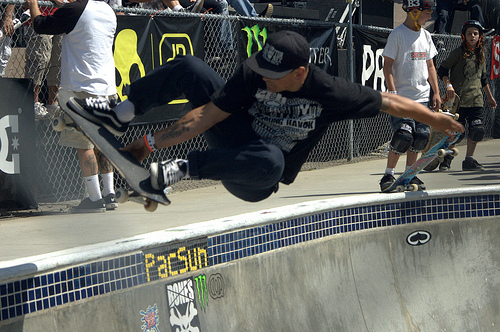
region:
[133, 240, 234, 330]
Advertisements on the half pike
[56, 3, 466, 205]
Man skatingboarding wearing all black and white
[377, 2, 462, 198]
Young boy preparing to skateboard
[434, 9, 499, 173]
Young child watching other skateboarders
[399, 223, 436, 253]
Black spade with white background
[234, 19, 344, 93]
Monster advertisement along the fence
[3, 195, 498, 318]
Blue checkered trim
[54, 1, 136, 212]
Man talking to people in the crowd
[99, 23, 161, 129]
Large yellow skull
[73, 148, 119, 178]
Tattoos on the man's leg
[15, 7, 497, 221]
this guy is stunt skating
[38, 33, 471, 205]
he is a skateboarder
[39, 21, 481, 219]
this is a skateboard competition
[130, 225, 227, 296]
this is the name of event sponsor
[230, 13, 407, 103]
these are event advertisements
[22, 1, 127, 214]
this guy is looking at the spectators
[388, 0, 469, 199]
this kid is waiting his turn to skate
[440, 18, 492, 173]
this child is also preparing to skate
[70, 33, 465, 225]
this is a cool skate move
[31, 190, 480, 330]
this is a skate arena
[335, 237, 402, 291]
part of a surface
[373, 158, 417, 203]
part of a wheel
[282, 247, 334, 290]
part of a surafce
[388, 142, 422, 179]
part of a board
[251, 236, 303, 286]
part of a surface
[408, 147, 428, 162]
part of a board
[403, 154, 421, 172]
part of a board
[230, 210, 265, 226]
edge iof a surface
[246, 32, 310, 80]
A black and white hat.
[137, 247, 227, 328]
Decals on the side of ramp.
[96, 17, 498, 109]
Sponsor signs.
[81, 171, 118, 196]
Long white tube socks.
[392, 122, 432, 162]
A pair of black kneepads.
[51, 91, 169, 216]
A skateboard.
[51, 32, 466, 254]
A man doing a trick in the air on his skateboard.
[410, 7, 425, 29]
Yellow straps to a helmet.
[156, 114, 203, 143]
A dark colored tattoo.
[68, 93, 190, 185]
A pair of white and black shoes.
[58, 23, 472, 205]
this is a person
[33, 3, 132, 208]
this is a person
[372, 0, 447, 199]
this is a person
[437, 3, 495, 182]
this is a person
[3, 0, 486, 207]
this is a chain link fence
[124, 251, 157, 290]
a letter on the writing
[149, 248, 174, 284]
a letter on the writing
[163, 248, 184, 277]
a letter on the writing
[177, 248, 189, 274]
a letter on the writing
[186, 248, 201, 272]
a letter on the writing